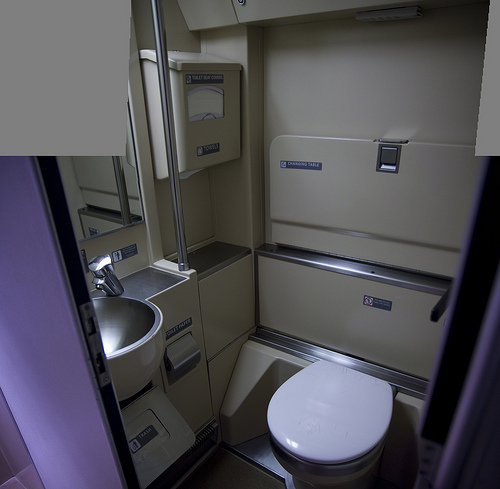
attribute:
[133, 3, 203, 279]
chromepole — long 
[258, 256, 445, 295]
metal — silver 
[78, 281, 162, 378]
sink — small 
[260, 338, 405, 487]
toilet — lid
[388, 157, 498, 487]
walls —  Lavendar 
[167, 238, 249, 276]
trashcan — small 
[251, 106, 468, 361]
table — fold out, changing table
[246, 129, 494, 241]
changing table — beige 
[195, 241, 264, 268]
part — Small 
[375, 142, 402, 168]
silver metal — small 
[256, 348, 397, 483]
toilet — seat cover dispenser 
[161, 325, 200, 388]
dispenser — toilet paper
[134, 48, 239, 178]
towel dispenser — Tan 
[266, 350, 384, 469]
toilet — white 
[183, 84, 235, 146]
paper towel —  paper 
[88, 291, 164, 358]
sink — beige 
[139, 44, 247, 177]
holder — beige 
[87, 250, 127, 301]
faucet — silver 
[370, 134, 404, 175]
latch — chrome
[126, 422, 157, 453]
sign — brown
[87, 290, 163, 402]
sink bowl — stainless steel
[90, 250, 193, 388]
sink — metal 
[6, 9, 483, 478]
bathroom —  airport 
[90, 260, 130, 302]
metal —  silver ,  Small part 